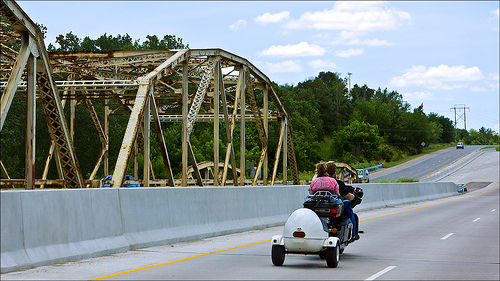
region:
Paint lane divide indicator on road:
[350, 203, 497, 279]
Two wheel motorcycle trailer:
[268, 208, 343, 268]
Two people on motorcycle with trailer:
[269, 161, 365, 268]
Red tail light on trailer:
[288, 229, 309, 241]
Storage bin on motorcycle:
[302, 196, 344, 220]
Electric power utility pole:
[445, 102, 472, 131]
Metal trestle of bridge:
[0, 4, 298, 184]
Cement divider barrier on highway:
[0, 178, 461, 274]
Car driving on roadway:
[452, 139, 467, 151]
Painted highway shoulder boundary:
[96, 174, 496, 279]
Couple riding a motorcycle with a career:
[264, 158, 374, 269]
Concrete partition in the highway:
[0, 173, 487, 274]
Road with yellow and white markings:
[42, 182, 498, 279]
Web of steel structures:
[0, 2, 303, 188]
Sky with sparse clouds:
[6, 0, 499, 135]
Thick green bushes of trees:
[0, 20, 497, 180]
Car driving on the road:
[453, 139, 466, 150]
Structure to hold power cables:
[447, 100, 472, 138]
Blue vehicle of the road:
[96, 170, 143, 188]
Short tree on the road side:
[326, 120, 392, 166]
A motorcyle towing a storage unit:
[257, 150, 379, 280]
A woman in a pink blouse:
[304, 161, 343, 198]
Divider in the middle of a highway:
[382, 172, 495, 207]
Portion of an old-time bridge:
[47, 23, 299, 211]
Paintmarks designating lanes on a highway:
[420, 203, 498, 243]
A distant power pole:
[438, 93, 477, 137]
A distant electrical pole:
[440, 97, 480, 139]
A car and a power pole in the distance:
[440, 94, 474, 156]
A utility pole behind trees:
[294, 56, 416, 151]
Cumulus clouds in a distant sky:
[242, 3, 492, 92]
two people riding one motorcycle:
[306, 157, 357, 202]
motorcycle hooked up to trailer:
[304, 187, 365, 256]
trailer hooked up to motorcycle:
[269, 206, 343, 270]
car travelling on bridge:
[99, 172, 138, 186]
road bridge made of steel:
[0, 0, 302, 188]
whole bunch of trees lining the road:
[1, 3, 498, 189]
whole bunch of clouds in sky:
[228, 0, 499, 136]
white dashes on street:
[361, 199, 498, 279]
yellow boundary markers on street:
[69, 179, 499, 278]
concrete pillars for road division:
[0, 179, 462, 276]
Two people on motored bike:
[279, 150, 382, 269]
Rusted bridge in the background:
[5, 0, 308, 204]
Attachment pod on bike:
[252, 201, 357, 274]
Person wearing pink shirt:
[303, 171, 344, 193]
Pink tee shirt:
[301, 171, 344, 196]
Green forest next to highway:
[42, 30, 477, 162]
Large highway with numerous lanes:
[11, 140, 495, 277]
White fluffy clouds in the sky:
[184, 0, 477, 105]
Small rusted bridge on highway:
[0, 0, 296, 184]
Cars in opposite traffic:
[347, 120, 477, 182]